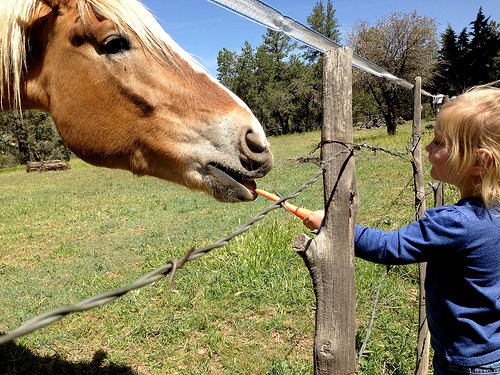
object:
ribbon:
[207, 0, 445, 105]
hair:
[430, 84, 500, 210]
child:
[301, 79, 499, 374]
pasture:
[0, 113, 462, 373]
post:
[290, 46, 357, 374]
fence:
[0, 0, 457, 374]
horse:
[0, 0, 275, 203]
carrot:
[253, 187, 313, 219]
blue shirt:
[353, 196, 499, 368]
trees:
[349, 8, 450, 136]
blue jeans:
[432, 361, 499, 374]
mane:
[0, 1, 44, 124]